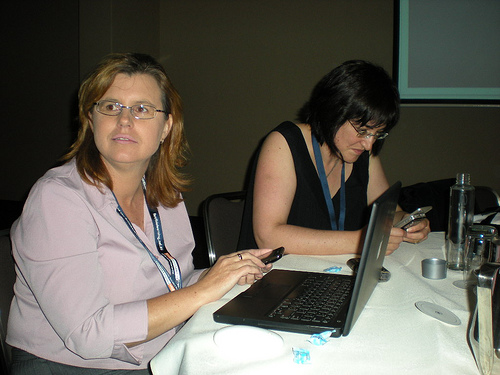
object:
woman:
[247, 58, 431, 257]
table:
[173, 232, 465, 373]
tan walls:
[112, 0, 393, 216]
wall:
[2, 0, 80, 232]